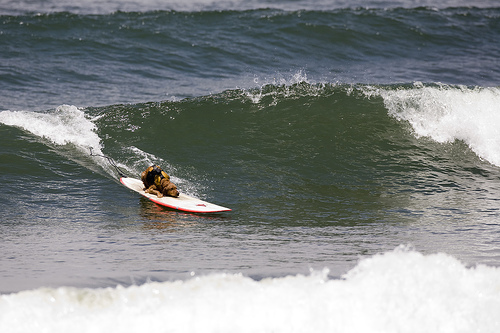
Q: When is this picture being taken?
A: Daytime.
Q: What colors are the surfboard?
A: Red and white.